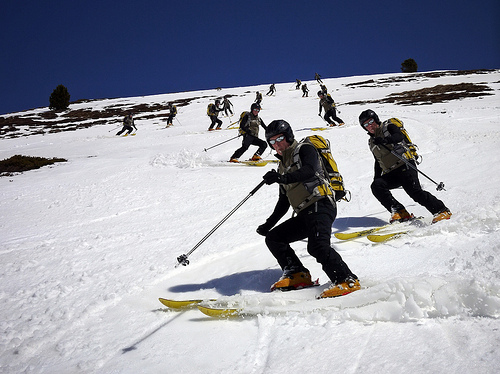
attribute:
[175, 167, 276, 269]
ski pole — silver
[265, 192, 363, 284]
pants — black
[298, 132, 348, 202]
backpack — yellow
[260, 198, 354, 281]
pants — long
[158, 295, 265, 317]
skis — yellow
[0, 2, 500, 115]
sky — clear, blue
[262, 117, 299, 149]
helmet — shiny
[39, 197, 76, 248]
snow — melted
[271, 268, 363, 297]
boots — ski